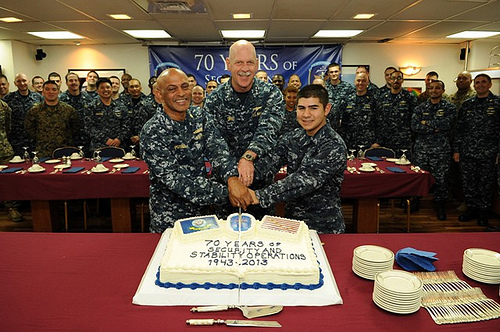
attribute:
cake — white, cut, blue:
[155, 212, 324, 291]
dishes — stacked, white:
[351, 243, 499, 315]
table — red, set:
[1, 231, 499, 331]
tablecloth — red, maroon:
[1, 233, 498, 331]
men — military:
[0, 38, 498, 233]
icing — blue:
[155, 266, 323, 291]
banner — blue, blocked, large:
[143, 42, 347, 90]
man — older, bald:
[203, 40, 285, 216]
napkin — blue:
[395, 246, 439, 271]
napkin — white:
[132, 227, 343, 308]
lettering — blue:
[190, 239, 308, 266]